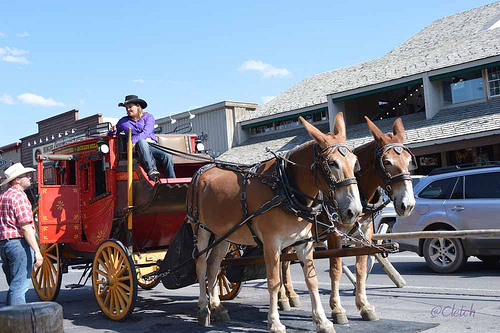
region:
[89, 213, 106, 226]
the carriage is red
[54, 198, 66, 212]
the carriage has flower designs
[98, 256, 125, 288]
the wheel is yellow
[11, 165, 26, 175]
the hat is white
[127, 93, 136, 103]
the hat is black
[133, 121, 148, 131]
the shirt is purple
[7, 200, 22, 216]
the shirt is red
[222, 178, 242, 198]
the mules are brown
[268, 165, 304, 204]
the harness is black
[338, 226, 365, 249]
the chain is gray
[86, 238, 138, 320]
yellow and black wheel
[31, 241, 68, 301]
yellow and black wheel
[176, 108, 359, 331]
brown and white horse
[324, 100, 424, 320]
brown and white horse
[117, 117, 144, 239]
yellow rod on cart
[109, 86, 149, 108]
black cowboy hat on man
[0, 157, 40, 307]
person with plaid shirt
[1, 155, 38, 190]
beige cowboy hat on man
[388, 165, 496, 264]
half of a silver car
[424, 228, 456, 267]
black and silver wheel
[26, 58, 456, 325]
two horses pulling a stagecoach replica down a city street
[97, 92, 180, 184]
a woman on a stage coach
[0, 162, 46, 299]
a man wearing a cowboy hat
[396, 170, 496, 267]
a silver car on a city street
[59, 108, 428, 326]
two horses pulling a stagecoach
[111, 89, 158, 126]
a woman wearing a black cowboy hat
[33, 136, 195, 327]
a red stagecoach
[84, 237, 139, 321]
the front wheel of a stagecoach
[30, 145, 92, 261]
an opened door on a stagecoach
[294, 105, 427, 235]
the heads of two horses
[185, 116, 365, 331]
this is a horse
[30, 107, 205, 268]
this is a stage coach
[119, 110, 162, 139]
man wearing a purple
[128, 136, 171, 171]
man wearing blue jeans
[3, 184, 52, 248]
man wearing plaid shirt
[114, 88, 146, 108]
man wearing a black hat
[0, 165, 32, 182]
man wearing a white hat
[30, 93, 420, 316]
horses pulling a stage coach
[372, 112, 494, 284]
this is a car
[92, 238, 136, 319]
Wheel on a carriage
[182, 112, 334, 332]
Animal on a carriage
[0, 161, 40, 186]
A cowboy hat being worn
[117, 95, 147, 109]
A black cowboy hat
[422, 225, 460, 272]
A rear right tire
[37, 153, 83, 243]
Door on a carriage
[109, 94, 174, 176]
Person driving a carriage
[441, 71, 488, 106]
Window on a building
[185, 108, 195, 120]
A light on a building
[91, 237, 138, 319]
A yellow wheel on a carriage